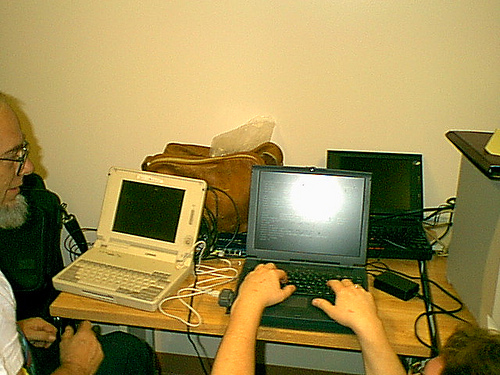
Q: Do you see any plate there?
A: No, there are no plates.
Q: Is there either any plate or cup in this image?
A: No, there are no plates or cups.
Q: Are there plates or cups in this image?
A: No, there are no plates or cups.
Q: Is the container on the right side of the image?
A: Yes, the container is on the right of the image.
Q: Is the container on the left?
A: No, the container is on the right of the image.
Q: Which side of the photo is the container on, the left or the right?
A: The container is on the right of the image.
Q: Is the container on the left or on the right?
A: The container is on the right of the image.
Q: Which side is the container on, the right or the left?
A: The container is on the right of the image.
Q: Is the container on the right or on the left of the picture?
A: The container is on the right of the image.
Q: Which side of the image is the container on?
A: The container is on the right of the image.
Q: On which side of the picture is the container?
A: The container is on the right of the image.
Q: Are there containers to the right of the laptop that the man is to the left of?
A: Yes, there is a container to the right of the laptop.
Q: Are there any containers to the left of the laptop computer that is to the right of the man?
A: No, the container is to the right of the laptop.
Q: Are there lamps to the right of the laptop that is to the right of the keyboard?
A: No, there is a container to the right of the laptop.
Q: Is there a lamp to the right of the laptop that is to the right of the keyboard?
A: No, there is a container to the right of the laptop.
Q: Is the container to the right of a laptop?
A: Yes, the container is to the right of a laptop.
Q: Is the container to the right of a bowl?
A: No, the container is to the right of a laptop.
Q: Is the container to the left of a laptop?
A: No, the container is to the right of a laptop.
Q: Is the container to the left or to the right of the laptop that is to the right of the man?
A: The container is to the right of the laptop.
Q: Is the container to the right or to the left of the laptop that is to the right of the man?
A: The container is to the right of the laptop.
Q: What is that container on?
A: The container is on the desk.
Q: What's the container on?
A: The container is on the desk.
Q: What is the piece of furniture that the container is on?
A: The piece of furniture is a desk.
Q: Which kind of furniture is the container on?
A: The container is on the desk.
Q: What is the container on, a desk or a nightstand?
A: The container is on a desk.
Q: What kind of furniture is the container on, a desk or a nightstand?
A: The container is on a desk.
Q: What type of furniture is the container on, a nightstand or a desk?
A: The container is on a desk.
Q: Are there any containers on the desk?
A: Yes, there is a container on the desk.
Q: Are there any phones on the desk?
A: No, there is a container on the desk.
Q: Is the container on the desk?
A: Yes, the container is on the desk.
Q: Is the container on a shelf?
A: No, the container is on the desk.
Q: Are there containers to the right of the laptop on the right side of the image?
A: Yes, there is a container to the right of the laptop.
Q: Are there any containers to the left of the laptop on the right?
A: No, the container is to the right of the laptop computer.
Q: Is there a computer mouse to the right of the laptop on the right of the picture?
A: No, there is a container to the right of the laptop.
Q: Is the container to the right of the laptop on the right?
A: Yes, the container is to the right of the laptop.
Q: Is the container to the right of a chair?
A: No, the container is to the right of the laptop.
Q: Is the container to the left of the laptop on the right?
A: No, the container is to the right of the laptop.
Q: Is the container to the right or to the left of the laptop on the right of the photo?
A: The container is to the right of the laptop computer.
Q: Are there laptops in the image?
A: Yes, there is a laptop.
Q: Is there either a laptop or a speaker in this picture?
A: Yes, there is a laptop.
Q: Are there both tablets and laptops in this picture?
A: No, there is a laptop but no tablets.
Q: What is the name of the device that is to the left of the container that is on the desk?
A: The device is a laptop.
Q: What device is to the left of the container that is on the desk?
A: The device is a laptop.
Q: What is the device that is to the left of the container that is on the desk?
A: The device is a laptop.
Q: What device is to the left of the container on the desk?
A: The device is a laptop.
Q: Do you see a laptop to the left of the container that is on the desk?
A: Yes, there is a laptop to the left of the container.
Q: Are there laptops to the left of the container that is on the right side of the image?
A: Yes, there is a laptop to the left of the container.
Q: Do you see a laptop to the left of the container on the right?
A: Yes, there is a laptop to the left of the container.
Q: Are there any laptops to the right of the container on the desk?
A: No, the laptop is to the left of the container.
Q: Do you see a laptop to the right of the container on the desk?
A: No, the laptop is to the left of the container.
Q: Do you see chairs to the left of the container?
A: No, there is a laptop to the left of the container.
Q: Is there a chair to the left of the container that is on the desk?
A: No, there is a laptop to the left of the container.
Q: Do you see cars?
A: No, there are no cars.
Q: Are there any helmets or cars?
A: No, there are no cars or helmets.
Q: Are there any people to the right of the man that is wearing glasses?
A: Yes, there is a person to the right of the man.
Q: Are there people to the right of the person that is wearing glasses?
A: Yes, there is a person to the right of the man.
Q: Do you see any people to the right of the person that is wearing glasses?
A: Yes, there is a person to the right of the man.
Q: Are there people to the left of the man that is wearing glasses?
A: No, the person is to the right of the man.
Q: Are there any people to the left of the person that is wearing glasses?
A: No, the person is to the right of the man.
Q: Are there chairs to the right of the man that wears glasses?
A: No, there is a person to the right of the man.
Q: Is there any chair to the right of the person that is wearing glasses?
A: No, there is a person to the right of the man.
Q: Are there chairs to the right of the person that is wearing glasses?
A: No, there is a person to the right of the man.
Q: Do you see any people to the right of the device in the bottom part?
A: Yes, there is a person to the right of the keyboard.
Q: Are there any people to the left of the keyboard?
A: No, the person is to the right of the keyboard.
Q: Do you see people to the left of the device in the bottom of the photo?
A: No, the person is to the right of the keyboard.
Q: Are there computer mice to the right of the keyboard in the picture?
A: No, there is a person to the right of the keyboard.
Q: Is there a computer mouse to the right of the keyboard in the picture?
A: No, there is a person to the right of the keyboard.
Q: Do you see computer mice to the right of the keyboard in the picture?
A: No, there is a person to the right of the keyboard.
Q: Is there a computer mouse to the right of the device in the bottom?
A: No, there is a person to the right of the keyboard.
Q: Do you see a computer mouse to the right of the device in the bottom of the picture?
A: No, there is a person to the right of the keyboard.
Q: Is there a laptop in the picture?
A: Yes, there is a laptop.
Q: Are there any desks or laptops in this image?
A: Yes, there is a laptop.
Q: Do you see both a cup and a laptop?
A: No, there is a laptop but no cups.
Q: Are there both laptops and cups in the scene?
A: No, there is a laptop but no cups.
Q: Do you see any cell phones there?
A: No, there are no cell phones.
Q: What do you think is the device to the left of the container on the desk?
A: The device is a laptop.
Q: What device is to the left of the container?
A: The device is a laptop.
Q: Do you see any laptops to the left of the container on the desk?
A: Yes, there is a laptop to the left of the container.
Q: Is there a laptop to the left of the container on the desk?
A: Yes, there is a laptop to the left of the container.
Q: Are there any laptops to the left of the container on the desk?
A: Yes, there is a laptop to the left of the container.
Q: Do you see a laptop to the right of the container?
A: No, the laptop is to the left of the container.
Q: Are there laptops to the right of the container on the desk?
A: No, the laptop is to the left of the container.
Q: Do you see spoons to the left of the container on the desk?
A: No, there is a laptop to the left of the container.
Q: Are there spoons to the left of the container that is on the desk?
A: No, there is a laptop to the left of the container.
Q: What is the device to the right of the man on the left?
A: The device is a laptop.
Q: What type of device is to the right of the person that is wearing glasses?
A: The device is a laptop.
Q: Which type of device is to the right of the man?
A: The device is a laptop.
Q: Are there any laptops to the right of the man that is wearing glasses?
A: Yes, there is a laptop to the right of the man.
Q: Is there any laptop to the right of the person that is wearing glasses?
A: Yes, there is a laptop to the right of the man.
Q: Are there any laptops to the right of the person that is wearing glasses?
A: Yes, there is a laptop to the right of the man.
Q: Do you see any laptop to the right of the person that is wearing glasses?
A: Yes, there is a laptop to the right of the man.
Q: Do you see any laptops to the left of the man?
A: No, the laptop is to the right of the man.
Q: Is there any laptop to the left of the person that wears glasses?
A: No, the laptop is to the right of the man.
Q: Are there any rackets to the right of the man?
A: No, there is a laptop to the right of the man.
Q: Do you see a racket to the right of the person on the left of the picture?
A: No, there is a laptop to the right of the man.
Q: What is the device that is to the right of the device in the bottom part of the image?
A: The device is a laptop.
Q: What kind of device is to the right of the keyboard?
A: The device is a laptop.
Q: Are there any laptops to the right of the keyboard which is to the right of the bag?
A: Yes, there is a laptop to the right of the keyboard.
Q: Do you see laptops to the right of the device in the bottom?
A: Yes, there is a laptop to the right of the keyboard.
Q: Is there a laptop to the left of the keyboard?
A: No, the laptop is to the right of the keyboard.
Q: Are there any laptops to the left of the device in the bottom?
A: No, the laptop is to the right of the keyboard.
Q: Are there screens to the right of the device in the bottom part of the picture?
A: No, there is a laptop to the right of the keyboard.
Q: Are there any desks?
A: Yes, there is a desk.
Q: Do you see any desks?
A: Yes, there is a desk.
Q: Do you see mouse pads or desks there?
A: Yes, there is a desk.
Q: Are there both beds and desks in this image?
A: No, there is a desk but no beds.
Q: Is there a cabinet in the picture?
A: No, there are no cabinets.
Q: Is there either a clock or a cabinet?
A: No, there are no cabinets or clocks.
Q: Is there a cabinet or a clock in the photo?
A: No, there are no cabinets or clocks.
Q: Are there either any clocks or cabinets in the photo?
A: No, there are no cabinets or clocks.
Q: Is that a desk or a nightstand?
A: That is a desk.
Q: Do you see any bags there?
A: Yes, there is a bag.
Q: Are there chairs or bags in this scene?
A: Yes, there is a bag.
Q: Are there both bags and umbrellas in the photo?
A: No, there is a bag but no umbrellas.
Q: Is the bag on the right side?
A: No, the bag is on the left of the image.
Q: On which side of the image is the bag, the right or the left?
A: The bag is on the left of the image.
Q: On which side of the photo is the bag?
A: The bag is on the left of the image.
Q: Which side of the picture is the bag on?
A: The bag is on the left of the image.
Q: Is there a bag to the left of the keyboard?
A: Yes, there is a bag to the left of the keyboard.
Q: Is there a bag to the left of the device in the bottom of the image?
A: Yes, there is a bag to the left of the keyboard.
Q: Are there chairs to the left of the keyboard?
A: No, there is a bag to the left of the keyboard.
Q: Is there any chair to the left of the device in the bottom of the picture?
A: No, there is a bag to the left of the keyboard.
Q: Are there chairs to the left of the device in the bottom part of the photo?
A: No, there is a bag to the left of the keyboard.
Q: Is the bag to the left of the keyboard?
A: Yes, the bag is to the left of the keyboard.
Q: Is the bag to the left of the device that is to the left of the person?
A: Yes, the bag is to the left of the keyboard.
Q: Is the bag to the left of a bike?
A: No, the bag is to the left of the keyboard.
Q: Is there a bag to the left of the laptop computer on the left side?
A: Yes, there is a bag to the left of the laptop.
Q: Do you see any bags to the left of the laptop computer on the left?
A: Yes, there is a bag to the left of the laptop.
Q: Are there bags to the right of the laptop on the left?
A: No, the bag is to the left of the laptop.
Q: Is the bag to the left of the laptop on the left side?
A: Yes, the bag is to the left of the laptop computer.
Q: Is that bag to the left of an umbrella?
A: No, the bag is to the left of the laptop computer.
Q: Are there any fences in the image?
A: No, there are no fences.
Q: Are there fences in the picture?
A: No, there are no fences.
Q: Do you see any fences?
A: No, there are no fences.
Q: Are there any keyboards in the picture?
A: Yes, there is a keyboard.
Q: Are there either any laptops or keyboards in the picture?
A: Yes, there is a keyboard.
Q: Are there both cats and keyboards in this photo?
A: No, there is a keyboard but no cats.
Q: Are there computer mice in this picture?
A: No, there are no computer mice.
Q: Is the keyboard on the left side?
A: Yes, the keyboard is on the left of the image.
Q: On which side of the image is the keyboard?
A: The keyboard is on the left of the image.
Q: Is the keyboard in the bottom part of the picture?
A: Yes, the keyboard is in the bottom of the image.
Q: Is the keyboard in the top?
A: No, the keyboard is in the bottom of the image.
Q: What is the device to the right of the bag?
A: The device is a keyboard.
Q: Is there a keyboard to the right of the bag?
A: Yes, there is a keyboard to the right of the bag.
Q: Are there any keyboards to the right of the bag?
A: Yes, there is a keyboard to the right of the bag.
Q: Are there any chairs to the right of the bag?
A: No, there is a keyboard to the right of the bag.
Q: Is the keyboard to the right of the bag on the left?
A: Yes, the keyboard is to the right of the bag.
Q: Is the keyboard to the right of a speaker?
A: No, the keyboard is to the right of the bag.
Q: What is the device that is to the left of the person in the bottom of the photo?
A: The device is a keyboard.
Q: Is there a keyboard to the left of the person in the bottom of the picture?
A: Yes, there is a keyboard to the left of the person.